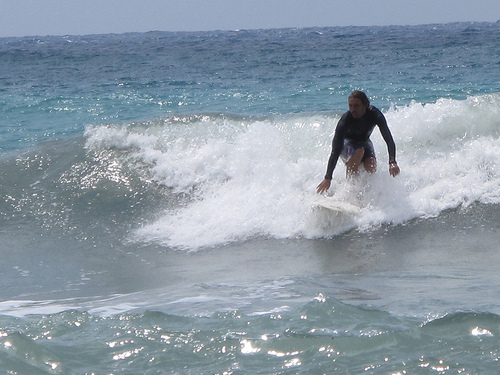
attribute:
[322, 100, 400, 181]
shirt — black, long sleeved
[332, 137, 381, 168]
bottoms — dark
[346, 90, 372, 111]
hair — black, dark, medium length, wet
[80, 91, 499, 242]
wave — white, small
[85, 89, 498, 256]
cap — white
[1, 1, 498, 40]
sky — blue, clear, pale blue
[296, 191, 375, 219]
surfboard — white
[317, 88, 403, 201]
person — young, surfing, wet, crouched, male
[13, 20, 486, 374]
water — clear blue, blue, clear, choppy, reflecting light, large